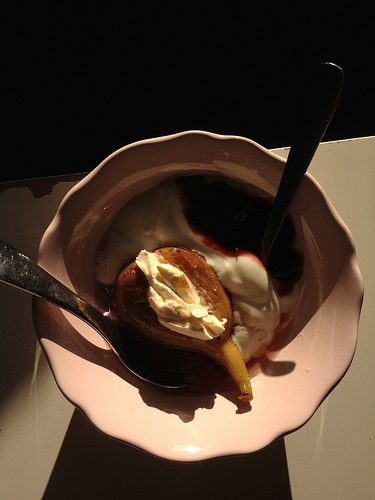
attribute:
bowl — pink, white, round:
[29, 125, 367, 465]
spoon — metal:
[0, 243, 201, 391]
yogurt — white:
[89, 183, 281, 363]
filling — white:
[136, 244, 225, 341]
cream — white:
[122, 198, 200, 251]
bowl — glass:
[34, 108, 372, 450]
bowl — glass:
[28, 123, 373, 414]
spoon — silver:
[2, 241, 224, 436]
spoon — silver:
[264, 71, 355, 343]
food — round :
[110, 227, 304, 411]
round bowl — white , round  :
[29, 113, 373, 470]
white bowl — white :
[31, 122, 366, 463]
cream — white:
[133, 247, 231, 341]